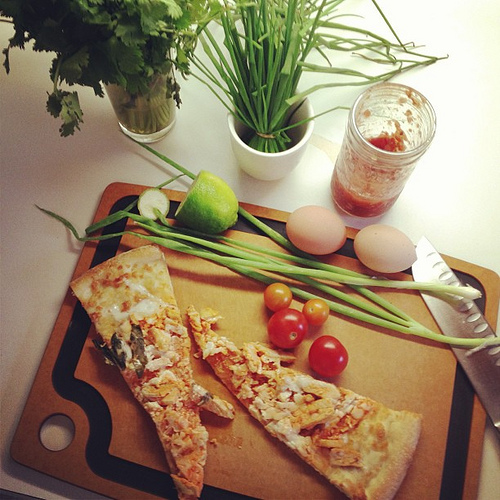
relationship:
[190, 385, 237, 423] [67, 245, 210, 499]
mushroom on pizza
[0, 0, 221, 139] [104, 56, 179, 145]
herbs in a glass jar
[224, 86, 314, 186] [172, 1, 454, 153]
cup holding herbs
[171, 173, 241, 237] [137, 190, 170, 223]
lime with a sliced off piece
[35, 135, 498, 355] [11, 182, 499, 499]
green onions on chopping board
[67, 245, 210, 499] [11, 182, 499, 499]
pizza on chopping board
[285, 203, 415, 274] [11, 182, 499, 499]
eggs on chopping board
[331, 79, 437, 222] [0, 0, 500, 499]
jar on counter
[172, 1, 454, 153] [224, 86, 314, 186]
chives in a cup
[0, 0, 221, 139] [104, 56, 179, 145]
parsley in a glass jar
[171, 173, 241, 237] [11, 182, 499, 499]
lime on a chopping board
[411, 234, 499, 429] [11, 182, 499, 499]
knife blade on chopping board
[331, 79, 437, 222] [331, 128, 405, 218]
jar of tomato suace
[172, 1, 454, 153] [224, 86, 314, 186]
chives in cup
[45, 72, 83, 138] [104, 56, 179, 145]
herbs in a glass jar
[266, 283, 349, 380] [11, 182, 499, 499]
tomatoes on chopping board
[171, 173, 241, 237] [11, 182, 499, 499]
lime on chopping board